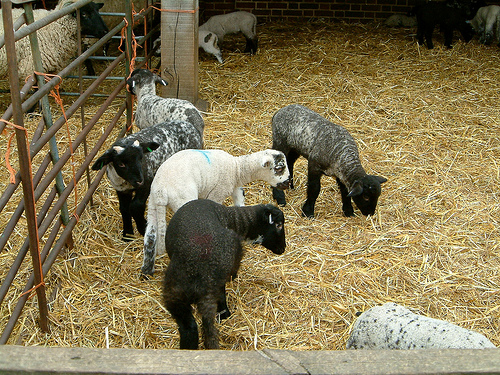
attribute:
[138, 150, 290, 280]
goat — black, white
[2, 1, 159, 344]
fence — metal, rusted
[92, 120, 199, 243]
sheep — spotted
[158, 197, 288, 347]
sheep — black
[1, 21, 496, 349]
hay — yellow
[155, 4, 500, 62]
baby goats — bunched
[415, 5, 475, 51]
baby goat — black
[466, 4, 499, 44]
baby goat — white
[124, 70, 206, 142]
baby goat — grey, white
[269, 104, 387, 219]
baby goat — black, white, gray, eating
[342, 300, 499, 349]
baby goat — spotted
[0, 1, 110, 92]
sheep — white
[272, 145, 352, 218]
legs — black